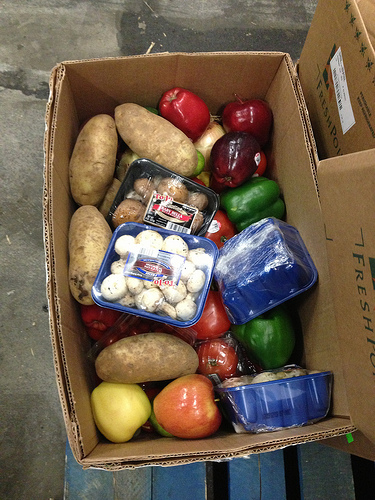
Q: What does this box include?
A: Fruits and vegetables.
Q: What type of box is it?
A: Cardboard.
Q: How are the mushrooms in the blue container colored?
A: White.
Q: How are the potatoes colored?
A: Brown.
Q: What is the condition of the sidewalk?
A: Very dirty.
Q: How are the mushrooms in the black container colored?
A: Brown.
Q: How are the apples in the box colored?
A: Red and yellow.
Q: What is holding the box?
A: Pallet.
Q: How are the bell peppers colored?
A: Green.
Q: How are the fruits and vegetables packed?
A: In a box.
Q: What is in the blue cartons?
A: Mushrooms.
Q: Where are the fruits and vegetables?
A: In a box.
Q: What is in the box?
A: Food.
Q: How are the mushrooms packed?
A: In cellophane.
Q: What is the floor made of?
A: Concrete.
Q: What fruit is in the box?
A: Apples.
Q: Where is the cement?
A: Ground.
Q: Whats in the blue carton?
A: Mushrooms.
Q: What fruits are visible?
A: Apples.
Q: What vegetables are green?
A: Peppers.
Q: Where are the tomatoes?
A: Underneath mushrooms.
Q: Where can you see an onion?
A: Between the apples.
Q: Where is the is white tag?
A: On box.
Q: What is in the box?
A: Vegetables.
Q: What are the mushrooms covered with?
A: Cellophane.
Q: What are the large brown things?
A: Potatoes.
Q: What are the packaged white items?
A: Mushrooms.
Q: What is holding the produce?
A: A cardboard box.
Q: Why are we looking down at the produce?
A: The camera is looking down.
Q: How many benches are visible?
A: One.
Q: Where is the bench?
A: Under the box.